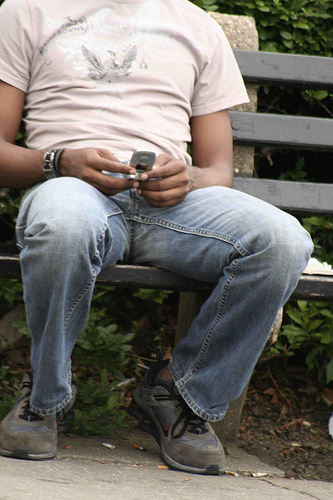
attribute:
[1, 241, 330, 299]
board — black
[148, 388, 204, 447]
laces — black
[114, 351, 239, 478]
shoe — grey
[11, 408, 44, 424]
laces — black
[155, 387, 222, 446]
laces — black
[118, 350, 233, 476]
shoe — grey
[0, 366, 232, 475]
shoe — grey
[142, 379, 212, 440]
laces — black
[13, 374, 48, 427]
laces — black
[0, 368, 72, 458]
shoe — grey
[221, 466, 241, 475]
but — cigarette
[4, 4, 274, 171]
shirt — pink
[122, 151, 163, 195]
cell phone — flip phone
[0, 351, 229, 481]
shoes — grey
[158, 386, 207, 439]
shoe string — black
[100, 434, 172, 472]
butt — cigarette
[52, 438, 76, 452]
butt — cigarette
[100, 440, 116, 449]
butt — cigarette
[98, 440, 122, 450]
butt — cigarette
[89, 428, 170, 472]
butt — cigarette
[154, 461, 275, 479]
butt — cigarette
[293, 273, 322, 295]
board — black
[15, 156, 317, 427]
jeans — blue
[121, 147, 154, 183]
phone — mobile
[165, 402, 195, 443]
shoelace — black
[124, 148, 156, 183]
mobile — silver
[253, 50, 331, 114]
bench — black, wood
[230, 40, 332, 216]
bench — wood, black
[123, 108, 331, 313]
bench — black, wood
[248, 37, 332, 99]
bench — black, wood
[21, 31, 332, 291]
bench — black, wood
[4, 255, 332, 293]
bench — black, wood